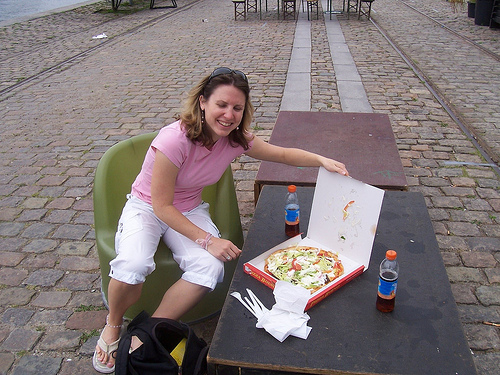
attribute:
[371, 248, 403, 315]
bottle — plastic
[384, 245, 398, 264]
cap — orange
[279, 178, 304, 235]
bottle — plastic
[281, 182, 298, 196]
cap — orange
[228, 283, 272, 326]
cutlery — white, plastic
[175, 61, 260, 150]
hair — brown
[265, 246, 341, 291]
pizza — small, cooked, baked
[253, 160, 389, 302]
box — open, cardboard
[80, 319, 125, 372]
flip flop — cream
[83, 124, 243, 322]
chair — green, plastic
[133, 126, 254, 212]
shirt — pink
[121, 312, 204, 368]
bag — black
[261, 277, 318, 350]
napkins — white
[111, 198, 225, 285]
pants — white